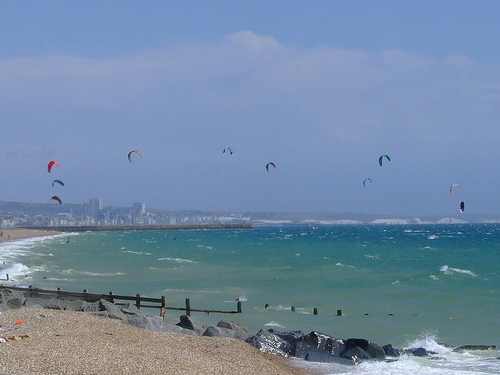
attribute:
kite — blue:
[48, 176, 69, 191]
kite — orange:
[124, 147, 144, 165]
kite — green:
[376, 150, 392, 168]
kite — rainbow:
[263, 160, 280, 173]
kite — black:
[457, 199, 466, 215]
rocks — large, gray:
[96, 295, 437, 361]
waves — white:
[0, 230, 79, 282]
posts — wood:
[3, 277, 373, 318]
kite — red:
[44, 154, 61, 174]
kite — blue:
[48, 178, 66, 188]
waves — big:
[0, 225, 89, 290]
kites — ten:
[45, 142, 466, 214]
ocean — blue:
[0, 220, 485, 372]